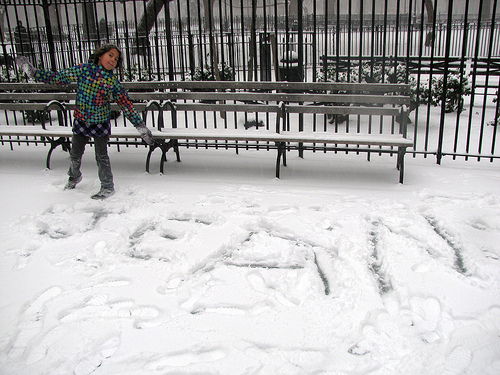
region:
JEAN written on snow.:
[29, 176, 498, 317]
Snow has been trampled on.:
[11, 179, 495, 374]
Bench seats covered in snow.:
[0, 67, 428, 172]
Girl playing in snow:
[12, 42, 167, 215]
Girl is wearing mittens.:
[8, 30, 163, 154]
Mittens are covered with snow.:
[14, 45, 169, 152]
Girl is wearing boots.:
[51, 137, 128, 213]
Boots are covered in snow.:
[58, 140, 120, 208]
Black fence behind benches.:
[0, 0, 499, 167]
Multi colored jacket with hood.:
[11, 37, 161, 146]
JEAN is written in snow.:
[27, 188, 487, 308]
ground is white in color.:
[59, 256, 260, 363]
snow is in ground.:
[42, 256, 188, 333]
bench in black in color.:
[151, 71, 426, 180]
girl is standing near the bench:
[53, 38, 135, 213]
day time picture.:
[16, 26, 426, 281]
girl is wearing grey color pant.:
[43, 143, 137, 195]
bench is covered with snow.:
[169, 120, 416, 157]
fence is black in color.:
[138, 13, 450, 70]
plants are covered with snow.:
[329, 63, 470, 98]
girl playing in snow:
[13, 35, 159, 210]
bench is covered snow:
[120, 72, 410, 159]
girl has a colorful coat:
[30, 57, 150, 124]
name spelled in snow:
[32, 190, 467, 296]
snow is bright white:
[15, 280, 475, 370]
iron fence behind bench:
[2, 11, 487, 166]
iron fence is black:
[5, 10, 490, 126]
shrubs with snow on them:
[325, 60, 470, 115]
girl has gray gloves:
[16, 46, 166, 152]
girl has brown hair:
[86, 41, 128, 71]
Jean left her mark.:
[45, 189, 476, 304]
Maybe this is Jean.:
[49, 40, 151, 207]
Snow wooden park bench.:
[159, 78, 416, 183]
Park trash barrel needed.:
[267, 38, 314, 99]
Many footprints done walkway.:
[10, 302, 486, 366]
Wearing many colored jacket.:
[71, 49, 128, 128]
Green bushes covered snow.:
[322, 63, 480, 126]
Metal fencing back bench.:
[331, 5, 495, 172]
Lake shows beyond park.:
[180, 27, 492, 74]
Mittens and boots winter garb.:
[95, 43, 157, 205]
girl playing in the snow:
[13, 42, 168, 200]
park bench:
[147, 74, 447, 185]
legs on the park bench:
[160, 140, 417, 177]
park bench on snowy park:
[174, 82, 415, 215]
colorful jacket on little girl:
[26, 61, 143, 136]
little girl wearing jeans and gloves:
[17, 40, 152, 207]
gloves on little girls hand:
[135, 118, 162, 150]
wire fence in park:
[237, 1, 482, 86]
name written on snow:
[37, 187, 473, 322]